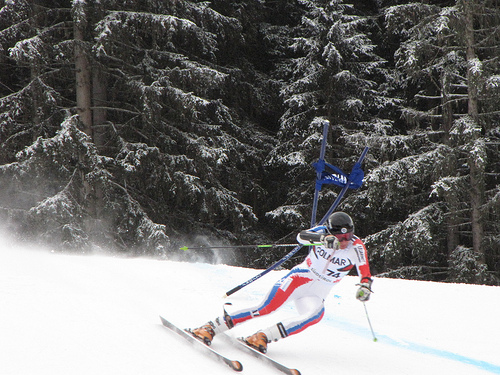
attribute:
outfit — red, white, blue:
[209, 227, 371, 341]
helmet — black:
[323, 212, 363, 244]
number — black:
[327, 267, 338, 280]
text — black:
[327, 270, 338, 278]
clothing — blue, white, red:
[215, 226, 371, 347]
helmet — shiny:
[323, 206, 356, 243]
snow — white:
[14, 268, 104, 348]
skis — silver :
[155, 307, 297, 373]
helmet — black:
[323, 210, 362, 232]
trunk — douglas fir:
[428, 32, 497, 292]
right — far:
[429, 15, 496, 265]